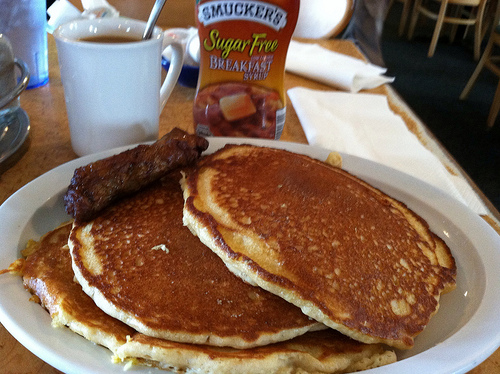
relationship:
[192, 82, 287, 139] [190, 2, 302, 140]
picture on bottle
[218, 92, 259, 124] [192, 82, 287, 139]
butter on picture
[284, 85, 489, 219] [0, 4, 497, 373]
handkerchief on table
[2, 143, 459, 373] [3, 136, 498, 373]
pancakes on plate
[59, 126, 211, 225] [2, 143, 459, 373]
sausage by pancakes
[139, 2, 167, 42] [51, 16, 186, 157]
spoon in cup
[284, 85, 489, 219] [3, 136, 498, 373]
napkin by plate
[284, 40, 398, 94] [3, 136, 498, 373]
napkin by plate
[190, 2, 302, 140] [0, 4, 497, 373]
bottle on table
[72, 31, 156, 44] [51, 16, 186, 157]
coffee in cup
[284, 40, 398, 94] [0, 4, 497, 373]
napkin on table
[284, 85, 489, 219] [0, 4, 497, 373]
napkin on table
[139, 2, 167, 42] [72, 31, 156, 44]
spoon in coffee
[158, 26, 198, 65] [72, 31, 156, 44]
creamer for coffee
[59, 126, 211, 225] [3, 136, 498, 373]
sausage on plate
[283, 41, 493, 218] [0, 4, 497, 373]
napkins on table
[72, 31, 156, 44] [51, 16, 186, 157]
coffee in mug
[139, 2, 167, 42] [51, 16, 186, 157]
spoon in mug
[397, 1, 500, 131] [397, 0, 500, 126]
legs of chairs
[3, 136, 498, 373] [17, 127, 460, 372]
plate of food